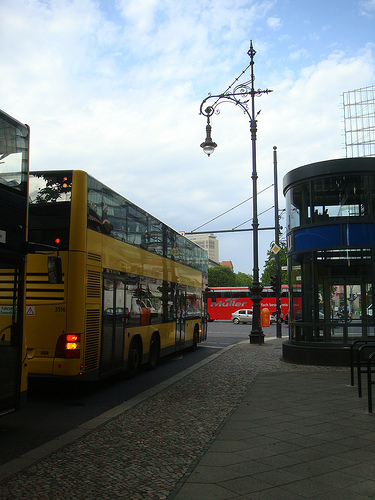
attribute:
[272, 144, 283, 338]
post — black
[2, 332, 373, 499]
sidewalk — cobble stone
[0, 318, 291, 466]
road — busy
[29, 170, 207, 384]
bus — parked, golden, yellow, large, double decker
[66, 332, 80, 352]
tail light — red, orange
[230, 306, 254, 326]
car — gray, silver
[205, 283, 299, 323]
bus — red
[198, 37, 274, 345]
light post — black, tall, fancy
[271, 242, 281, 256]
sign — diamond shaped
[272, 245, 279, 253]
diamond — yellow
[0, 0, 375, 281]
sky — blue, cloudy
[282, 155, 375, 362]
building — round, glass, entrance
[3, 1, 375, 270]
clouds — white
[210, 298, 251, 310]
logo — "muller"